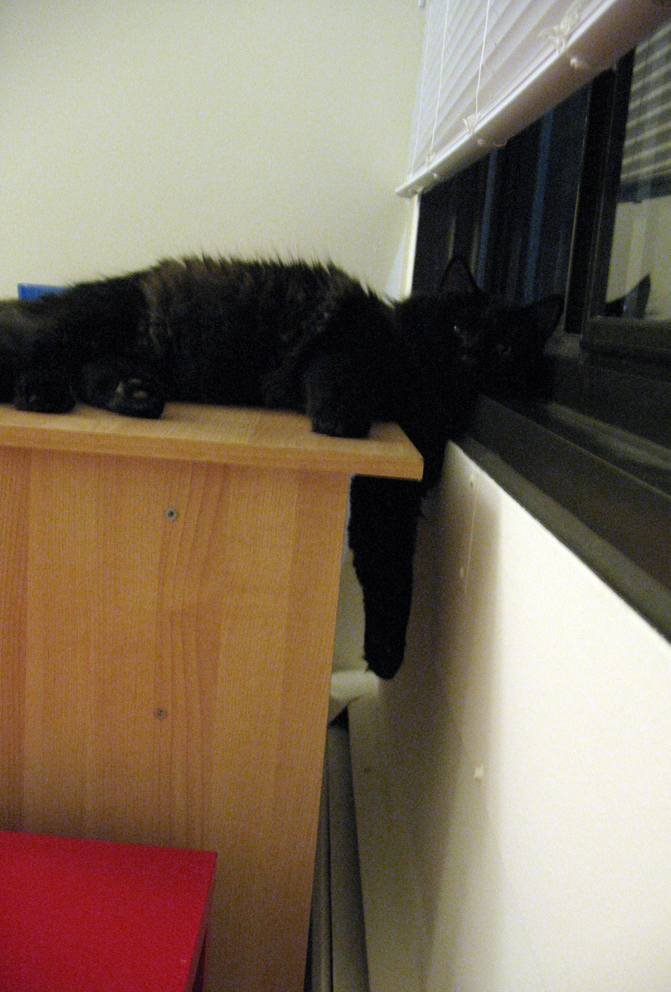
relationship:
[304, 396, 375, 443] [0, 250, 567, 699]
paw on cat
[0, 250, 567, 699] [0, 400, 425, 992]
cat on desk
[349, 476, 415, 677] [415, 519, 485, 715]
cat paw on wall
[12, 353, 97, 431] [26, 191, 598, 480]
paw on cat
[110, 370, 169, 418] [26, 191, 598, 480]
paw on cat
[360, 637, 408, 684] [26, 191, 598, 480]
paw on cat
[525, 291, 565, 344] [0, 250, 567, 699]
ear of cat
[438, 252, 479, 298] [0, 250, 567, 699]
ear of cat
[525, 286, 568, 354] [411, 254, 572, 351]
ear on cat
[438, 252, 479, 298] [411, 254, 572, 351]
ear on cat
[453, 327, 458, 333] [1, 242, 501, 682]
cateye belongs to cat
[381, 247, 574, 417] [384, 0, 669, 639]
cat head on window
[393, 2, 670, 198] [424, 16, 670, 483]
blinds on window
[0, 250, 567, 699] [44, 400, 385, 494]
cat on desk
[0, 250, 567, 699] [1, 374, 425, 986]
cat laying on desk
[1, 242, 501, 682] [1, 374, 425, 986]
cat laying on desk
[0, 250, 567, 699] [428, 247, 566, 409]
cat with cat head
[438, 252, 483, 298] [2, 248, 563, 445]
ear on cat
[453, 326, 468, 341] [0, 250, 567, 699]
cateye on cat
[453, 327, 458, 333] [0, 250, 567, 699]
cateye belongs to cat